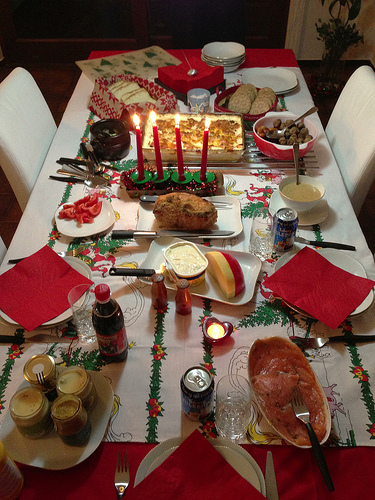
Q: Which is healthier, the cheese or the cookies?
A: The cheese is healthier than the cookies.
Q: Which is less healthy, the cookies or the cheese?
A: The cookies is less healthy than the cheese.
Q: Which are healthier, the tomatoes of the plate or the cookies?
A: The tomatoes are healthier than the cookies.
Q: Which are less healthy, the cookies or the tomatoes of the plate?
A: The cookies are less healthy than the tomatoes.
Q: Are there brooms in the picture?
A: No, there are no brooms.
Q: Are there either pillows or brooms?
A: No, there are no brooms or pillows.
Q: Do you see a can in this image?
A: Yes, there is a can.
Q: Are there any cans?
A: Yes, there is a can.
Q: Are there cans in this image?
A: Yes, there is a can.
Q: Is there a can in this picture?
A: Yes, there is a can.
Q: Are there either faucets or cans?
A: Yes, there is a can.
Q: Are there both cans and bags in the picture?
A: No, there is a can but no bags.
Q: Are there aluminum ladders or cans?
A: Yes, there is an aluminum can.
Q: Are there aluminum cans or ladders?
A: Yes, there is an aluminum can.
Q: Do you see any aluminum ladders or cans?
A: Yes, there is an aluminum can.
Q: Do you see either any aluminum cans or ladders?
A: Yes, there is an aluminum can.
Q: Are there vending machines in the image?
A: No, there are no vending machines.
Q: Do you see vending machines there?
A: No, there are no vending machines.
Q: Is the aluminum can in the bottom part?
A: Yes, the can is in the bottom of the image.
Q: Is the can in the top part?
A: No, the can is in the bottom of the image.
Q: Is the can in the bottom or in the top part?
A: The can is in the bottom of the image.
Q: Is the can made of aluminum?
A: Yes, the can is made of aluminum.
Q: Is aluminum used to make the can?
A: Yes, the can is made of aluminum.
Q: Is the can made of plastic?
A: No, the can is made of aluminum.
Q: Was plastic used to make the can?
A: No, the can is made of aluminum.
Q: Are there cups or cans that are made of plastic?
A: No, there is a can but it is made of aluminum.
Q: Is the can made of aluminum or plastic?
A: The can is made of aluminum.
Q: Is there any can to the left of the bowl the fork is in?
A: Yes, there is a can to the left of the bowl.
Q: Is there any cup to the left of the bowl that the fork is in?
A: No, there is a can to the left of the bowl.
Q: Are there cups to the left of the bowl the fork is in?
A: No, there is a can to the left of the bowl.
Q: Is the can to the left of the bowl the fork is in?
A: Yes, the can is to the left of the bowl.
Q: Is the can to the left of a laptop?
A: No, the can is to the left of the bowl.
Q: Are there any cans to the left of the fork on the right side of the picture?
A: Yes, there is a can to the left of the fork.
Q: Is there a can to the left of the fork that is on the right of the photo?
A: Yes, there is a can to the left of the fork.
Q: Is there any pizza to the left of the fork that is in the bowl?
A: No, there is a can to the left of the fork.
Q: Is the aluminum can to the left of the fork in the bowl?
A: Yes, the can is to the left of the fork.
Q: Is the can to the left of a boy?
A: No, the can is to the left of the fork.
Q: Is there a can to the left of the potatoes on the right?
A: Yes, there is a can to the left of the potatoes.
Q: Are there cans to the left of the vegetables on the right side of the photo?
A: Yes, there is a can to the left of the potatoes.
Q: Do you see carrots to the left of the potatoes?
A: No, there is a can to the left of the potatoes.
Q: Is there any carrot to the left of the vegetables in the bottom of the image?
A: No, there is a can to the left of the potatoes.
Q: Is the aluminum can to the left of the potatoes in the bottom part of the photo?
A: Yes, the can is to the left of the potatoes.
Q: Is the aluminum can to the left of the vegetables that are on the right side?
A: Yes, the can is to the left of the potatoes.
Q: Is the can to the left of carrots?
A: No, the can is to the left of the potatoes.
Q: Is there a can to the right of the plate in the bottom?
A: Yes, there is a can to the right of the plate.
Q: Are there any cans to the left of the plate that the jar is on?
A: No, the can is to the right of the plate.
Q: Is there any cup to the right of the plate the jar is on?
A: No, there is a can to the right of the plate.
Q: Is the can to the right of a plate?
A: Yes, the can is to the right of a plate.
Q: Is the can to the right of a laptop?
A: No, the can is to the right of a plate.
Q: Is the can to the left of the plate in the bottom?
A: No, the can is to the right of the plate.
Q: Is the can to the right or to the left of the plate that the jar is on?
A: The can is to the right of the plate.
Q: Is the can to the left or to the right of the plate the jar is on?
A: The can is to the right of the plate.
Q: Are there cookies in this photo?
A: Yes, there are cookies.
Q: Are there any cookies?
A: Yes, there are cookies.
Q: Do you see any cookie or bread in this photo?
A: Yes, there are cookies.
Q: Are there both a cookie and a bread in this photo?
A: Yes, there are both a cookie and a bread.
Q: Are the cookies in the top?
A: Yes, the cookies are in the top of the image.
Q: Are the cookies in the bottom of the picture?
A: No, the cookies are in the top of the image.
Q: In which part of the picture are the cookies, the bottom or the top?
A: The cookies are in the top of the image.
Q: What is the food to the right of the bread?
A: The food is cookies.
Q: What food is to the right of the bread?
A: The food is cookies.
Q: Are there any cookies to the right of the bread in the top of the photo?
A: Yes, there are cookies to the right of the bread.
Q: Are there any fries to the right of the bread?
A: No, there are cookies to the right of the bread.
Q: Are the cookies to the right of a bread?
A: Yes, the cookies are to the right of a bread.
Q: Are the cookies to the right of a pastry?
A: No, the cookies are to the right of a bread.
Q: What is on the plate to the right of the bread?
A: The cookies are on the plate.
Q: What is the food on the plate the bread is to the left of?
A: The food is cookies.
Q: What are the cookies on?
A: The cookies are on the plate.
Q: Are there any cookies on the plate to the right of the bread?
A: Yes, there are cookies on the plate.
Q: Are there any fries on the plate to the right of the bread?
A: No, there are cookies on the plate.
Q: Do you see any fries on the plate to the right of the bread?
A: No, there are cookies on the plate.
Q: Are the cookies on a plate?
A: Yes, the cookies are on a plate.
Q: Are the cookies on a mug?
A: No, the cookies are on a plate.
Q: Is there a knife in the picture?
A: Yes, there is a knife.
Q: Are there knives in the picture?
A: Yes, there is a knife.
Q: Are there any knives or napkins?
A: Yes, there is a knife.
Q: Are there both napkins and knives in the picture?
A: Yes, there are both a knife and a napkin.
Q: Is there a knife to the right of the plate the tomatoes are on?
A: Yes, there is a knife to the right of the plate.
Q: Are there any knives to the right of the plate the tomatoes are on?
A: Yes, there is a knife to the right of the plate.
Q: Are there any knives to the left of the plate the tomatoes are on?
A: No, the knife is to the right of the plate.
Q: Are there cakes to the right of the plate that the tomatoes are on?
A: No, there is a knife to the right of the plate.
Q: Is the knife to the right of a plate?
A: Yes, the knife is to the right of a plate.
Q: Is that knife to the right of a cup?
A: No, the knife is to the right of a plate.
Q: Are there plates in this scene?
A: Yes, there is a plate.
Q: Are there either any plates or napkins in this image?
A: Yes, there is a plate.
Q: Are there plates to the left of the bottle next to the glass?
A: Yes, there is a plate to the left of the bottle.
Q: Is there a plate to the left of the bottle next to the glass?
A: Yes, there is a plate to the left of the bottle.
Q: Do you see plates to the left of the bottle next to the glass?
A: Yes, there is a plate to the left of the bottle.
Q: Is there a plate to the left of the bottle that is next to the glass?
A: Yes, there is a plate to the left of the bottle.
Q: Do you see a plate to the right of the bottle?
A: No, the plate is to the left of the bottle.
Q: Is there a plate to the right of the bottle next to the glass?
A: No, the plate is to the left of the bottle.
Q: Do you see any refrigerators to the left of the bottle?
A: No, there is a plate to the left of the bottle.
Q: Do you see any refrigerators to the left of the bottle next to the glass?
A: No, there is a plate to the left of the bottle.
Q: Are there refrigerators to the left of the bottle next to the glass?
A: No, there is a plate to the left of the bottle.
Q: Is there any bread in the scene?
A: Yes, there is a bread.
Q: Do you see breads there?
A: Yes, there is a bread.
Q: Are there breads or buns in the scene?
A: Yes, there is a bread.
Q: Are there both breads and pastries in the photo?
A: No, there is a bread but no pastries.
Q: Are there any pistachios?
A: No, there are no pistachios.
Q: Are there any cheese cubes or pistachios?
A: No, there are no pistachios or cheese cubes.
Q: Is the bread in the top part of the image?
A: Yes, the bread is in the top of the image.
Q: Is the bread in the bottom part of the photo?
A: No, the bread is in the top of the image.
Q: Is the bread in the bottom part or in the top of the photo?
A: The bread is in the top of the image.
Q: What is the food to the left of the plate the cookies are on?
A: The food is a bread.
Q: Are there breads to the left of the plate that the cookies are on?
A: Yes, there is a bread to the left of the plate.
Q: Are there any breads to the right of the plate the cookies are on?
A: No, the bread is to the left of the plate.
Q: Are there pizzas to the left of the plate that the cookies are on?
A: No, there is a bread to the left of the plate.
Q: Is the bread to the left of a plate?
A: Yes, the bread is to the left of a plate.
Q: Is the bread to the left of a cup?
A: No, the bread is to the left of a plate.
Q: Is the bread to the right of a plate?
A: No, the bread is to the left of a plate.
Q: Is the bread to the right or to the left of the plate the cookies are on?
A: The bread is to the left of the plate.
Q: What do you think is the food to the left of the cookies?
A: The food is a bread.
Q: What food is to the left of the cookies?
A: The food is a bread.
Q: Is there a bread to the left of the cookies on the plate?
A: Yes, there is a bread to the left of the cookies.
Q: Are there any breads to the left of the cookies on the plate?
A: Yes, there is a bread to the left of the cookies.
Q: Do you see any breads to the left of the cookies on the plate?
A: Yes, there is a bread to the left of the cookies.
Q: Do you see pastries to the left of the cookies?
A: No, there is a bread to the left of the cookies.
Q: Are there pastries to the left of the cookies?
A: No, there is a bread to the left of the cookies.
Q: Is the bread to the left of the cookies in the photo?
A: Yes, the bread is to the left of the cookies.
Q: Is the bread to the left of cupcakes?
A: No, the bread is to the left of the cookies.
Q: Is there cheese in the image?
A: Yes, there is cheese.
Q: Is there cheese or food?
A: Yes, there is cheese.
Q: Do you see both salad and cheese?
A: No, there is cheese but no salad.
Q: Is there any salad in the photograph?
A: No, there is no salad.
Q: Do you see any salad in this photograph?
A: No, there is no salad.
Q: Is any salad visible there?
A: No, there is no salad.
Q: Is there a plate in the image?
A: Yes, there is a plate.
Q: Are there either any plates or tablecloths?
A: Yes, there is a plate.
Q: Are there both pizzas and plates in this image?
A: No, there is a plate but no pizzas.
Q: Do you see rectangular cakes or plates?
A: Yes, there is a rectangular plate.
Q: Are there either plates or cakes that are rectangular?
A: Yes, the plate is rectangular.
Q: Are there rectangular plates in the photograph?
A: Yes, there is a rectangular plate.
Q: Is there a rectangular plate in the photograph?
A: Yes, there is a rectangular plate.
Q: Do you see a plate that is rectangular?
A: Yes, there is a plate that is rectangular.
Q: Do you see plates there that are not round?
A: Yes, there is a rectangular plate.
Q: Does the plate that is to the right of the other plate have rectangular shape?
A: Yes, the plate is rectangular.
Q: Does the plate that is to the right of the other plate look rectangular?
A: Yes, the plate is rectangular.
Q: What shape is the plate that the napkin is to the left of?
A: The plate is rectangular.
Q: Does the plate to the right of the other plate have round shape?
A: No, the plate is rectangular.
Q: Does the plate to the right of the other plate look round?
A: No, the plate is rectangular.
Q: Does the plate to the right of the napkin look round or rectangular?
A: The plate is rectangular.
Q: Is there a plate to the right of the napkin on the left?
A: Yes, there is a plate to the right of the napkin.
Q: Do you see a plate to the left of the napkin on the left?
A: No, the plate is to the right of the napkin.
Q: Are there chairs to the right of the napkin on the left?
A: No, there is a plate to the right of the napkin.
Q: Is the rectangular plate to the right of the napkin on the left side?
A: Yes, the plate is to the right of the napkin.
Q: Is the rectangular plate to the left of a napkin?
A: No, the plate is to the right of a napkin.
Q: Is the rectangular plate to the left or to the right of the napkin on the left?
A: The plate is to the right of the napkin.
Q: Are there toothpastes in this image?
A: No, there are no toothpastes.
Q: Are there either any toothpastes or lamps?
A: No, there are no toothpastes or lamps.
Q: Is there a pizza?
A: No, there are no pizzas.